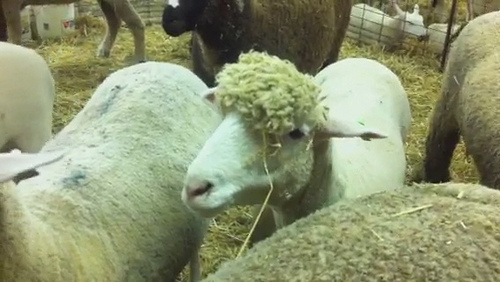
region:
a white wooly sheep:
[179, 57, 410, 234]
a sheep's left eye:
[288, 125, 309, 142]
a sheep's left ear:
[317, 105, 389, 140]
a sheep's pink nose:
[181, 174, 218, 199]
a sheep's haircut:
[217, 46, 315, 133]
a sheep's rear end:
[2, 63, 221, 280]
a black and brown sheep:
[158, 0, 350, 81]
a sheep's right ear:
[204, 82, 244, 116]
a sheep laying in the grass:
[344, 5, 426, 52]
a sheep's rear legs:
[92, 0, 149, 58]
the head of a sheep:
[181, 43, 395, 221]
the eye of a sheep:
[269, 108, 334, 158]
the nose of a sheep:
[169, 145, 245, 225]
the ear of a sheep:
[276, 82, 407, 170]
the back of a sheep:
[23, 0, 228, 232]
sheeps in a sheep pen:
[169, 8, 481, 242]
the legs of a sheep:
[85, 0, 187, 97]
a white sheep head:
[185, 68, 395, 211]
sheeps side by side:
[60, 12, 497, 259]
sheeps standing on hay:
[159, 15, 487, 273]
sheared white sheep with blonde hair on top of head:
[177, 44, 404, 216]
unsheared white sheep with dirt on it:
[7, 56, 249, 280]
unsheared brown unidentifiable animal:
[159, 2, 370, 82]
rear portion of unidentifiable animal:
[0, 39, 52, 152]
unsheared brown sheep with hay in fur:
[199, 180, 497, 278]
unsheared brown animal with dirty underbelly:
[423, 10, 498, 188]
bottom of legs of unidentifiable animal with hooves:
[0, 1, 152, 62]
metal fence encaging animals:
[347, 3, 453, 52]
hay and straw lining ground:
[27, 15, 480, 280]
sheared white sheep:
[349, 0, 429, 48]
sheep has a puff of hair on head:
[208, 52, 394, 165]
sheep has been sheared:
[103, 108, 197, 260]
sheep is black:
[171, 4, 369, 84]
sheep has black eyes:
[277, 127, 321, 152]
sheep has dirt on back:
[341, 180, 480, 272]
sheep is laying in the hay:
[365, 7, 428, 53]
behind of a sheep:
[8, 38, 56, 139]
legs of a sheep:
[81, 2, 159, 77]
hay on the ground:
[51, 32, 179, 104]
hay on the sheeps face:
[241, 118, 306, 278]